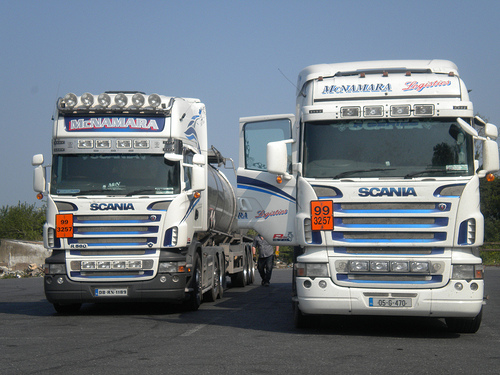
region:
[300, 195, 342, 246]
orange and black sign with 99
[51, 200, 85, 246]
orange and black sign on left truck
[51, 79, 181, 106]
light bar on top of truck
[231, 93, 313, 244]
open door of truck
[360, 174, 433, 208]
blue lettering on front of right truck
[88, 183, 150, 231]
blue lettering on front of left truck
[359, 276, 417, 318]
license plate on front of right truck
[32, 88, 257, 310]
a large truck parked on the road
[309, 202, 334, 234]
an orange sign with numbers on it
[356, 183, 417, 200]
a logo on the front of a truck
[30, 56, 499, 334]
two trucks parked side by side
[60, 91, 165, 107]
lights along the top of a truck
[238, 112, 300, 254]
a truck door wide open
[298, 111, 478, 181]
front window of a truck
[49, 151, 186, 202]
window into a truck cab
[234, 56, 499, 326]
large truck with open door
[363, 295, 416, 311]
license plate on a truck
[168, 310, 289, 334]
shadow cast on the ground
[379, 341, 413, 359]
small black spot on the road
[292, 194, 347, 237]
small orange sign on the front of truck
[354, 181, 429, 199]
blue label on front of truck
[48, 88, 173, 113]
row of lights at top of truck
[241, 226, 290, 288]
man walking on the ground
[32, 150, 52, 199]
large mirror at side of truck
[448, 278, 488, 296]
small row of lights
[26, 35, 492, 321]
large trucks on the road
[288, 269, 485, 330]
white bumper on front of the truck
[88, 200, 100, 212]
blue letter on truck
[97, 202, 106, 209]
blue letter on truck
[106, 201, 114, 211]
blue letter on truck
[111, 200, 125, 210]
blue letter on truck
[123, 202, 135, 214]
blue letter on truck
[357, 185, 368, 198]
blue letter on truck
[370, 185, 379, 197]
blue letter on truck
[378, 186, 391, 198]
blue letter on truck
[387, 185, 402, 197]
blue letter on truck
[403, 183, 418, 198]
blue letter on truck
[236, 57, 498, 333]
a large truck with an open door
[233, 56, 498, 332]
a truck on the road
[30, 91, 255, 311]
a truck with a silver tank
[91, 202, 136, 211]
a logo on the front of a truck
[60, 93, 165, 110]
a row of lights on a truck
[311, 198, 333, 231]
an orange sign with numbers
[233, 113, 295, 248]
an open truck door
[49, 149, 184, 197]
a window on the front of a truck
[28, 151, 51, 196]
a mirror on the side of a truck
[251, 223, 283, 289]
a man walking on the road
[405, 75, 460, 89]
RED WRITING ON THE TRUCK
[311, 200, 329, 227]
SIGN ON THE FRONT OF TRUCK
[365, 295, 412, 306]
TAG ON THE TRUCK